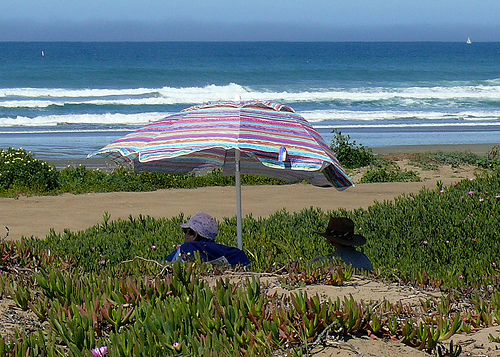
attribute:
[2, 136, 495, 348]
beach — swamp, large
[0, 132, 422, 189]
plants — green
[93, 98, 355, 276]
umbrella — striped, multi colored, open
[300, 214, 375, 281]
man — sittins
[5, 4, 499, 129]
ocean — calm, blue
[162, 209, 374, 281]
people — sitting, enjoying the beach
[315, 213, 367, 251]
hat — brown, cowboy style, cowboy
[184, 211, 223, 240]
hat — white, ball cap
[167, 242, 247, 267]
shirt — blue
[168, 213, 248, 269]
person — sitting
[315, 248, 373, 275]
shirt — blue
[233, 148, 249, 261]
pole — metal, white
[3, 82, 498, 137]
waves crashing — white sea foam, white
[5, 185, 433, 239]
path — sand, brown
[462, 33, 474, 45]
sail boat — white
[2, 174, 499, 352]
plants — green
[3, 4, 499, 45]
sky — blue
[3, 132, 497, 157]
sand — wet, brown